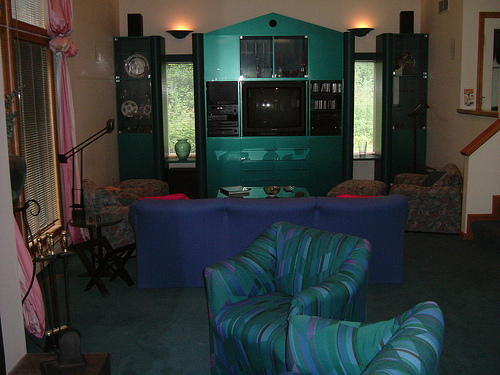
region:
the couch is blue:
[106, 187, 390, 281]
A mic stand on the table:
[43, 105, 121, 232]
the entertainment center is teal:
[187, 25, 350, 208]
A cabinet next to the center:
[113, 31, 182, 186]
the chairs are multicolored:
[234, 242, 386, 372]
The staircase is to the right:
[439, 109, 497, 251]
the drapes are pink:
[66, 30, 86, 223]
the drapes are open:
[13, 34, 99, 225]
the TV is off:
[245, 67, 314, 131]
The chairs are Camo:
[415, 170, 464, 235]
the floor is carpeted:
[88, 282, 202, 364]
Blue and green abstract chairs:
[182, 213, 464, 373]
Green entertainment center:
[185, 3, 370, 218]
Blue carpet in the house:
[29, 176, 499, 373]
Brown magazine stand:
[57, 216, 146, 294]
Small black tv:
[239, 79, 311, 138]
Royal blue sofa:
[109, 173, 433, 296]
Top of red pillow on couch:
[135, 190, 196, 211]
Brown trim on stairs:
[457, 107, 495, 172]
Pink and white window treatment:
[44, 3, 106, 255]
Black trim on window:
[347, 45, 397, 168]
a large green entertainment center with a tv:
[188, 4, 370, 200]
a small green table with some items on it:
[218, 177, 312, 203]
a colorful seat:
[199, 227, 370, 368]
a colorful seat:
[391, 160, 470, 244]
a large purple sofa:
[136, 190, 411, 289]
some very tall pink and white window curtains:
[54, 6, 74, 242]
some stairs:
[470, 182, 497, 252]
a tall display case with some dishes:
[116, 20, 156, 193]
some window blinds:
[20, 32, 55, 246]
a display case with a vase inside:
[164, 53, 199, 169]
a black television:
[213, 73, 326, 163]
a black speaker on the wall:
[53, 105, 143, 185]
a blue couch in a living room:
[125, 173, 481, 345]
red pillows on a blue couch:
[120, 175, 387, 215]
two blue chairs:
[206, 218, 447, 373]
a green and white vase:
[154, 124, 213, 180]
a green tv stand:
[151, 50, 386, 180]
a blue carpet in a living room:
[106, 300, 227, 369]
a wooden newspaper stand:
[62, 207, 131, 294]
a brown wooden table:
[11, 329, 116, 373]